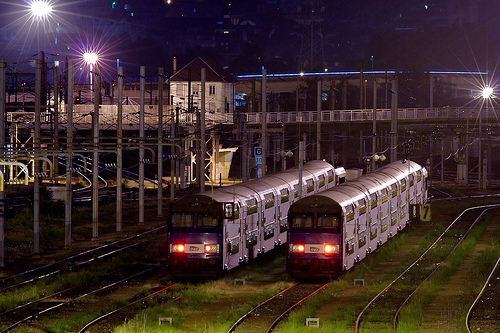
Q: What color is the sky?
A: Black.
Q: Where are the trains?
A: On the tracks.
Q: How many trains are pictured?
A: Two.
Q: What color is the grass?
A: Green.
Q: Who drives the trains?
A: Engineers.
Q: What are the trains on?
A: Tracks.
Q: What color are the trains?
A: Grey.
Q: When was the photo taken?
A: Night time.